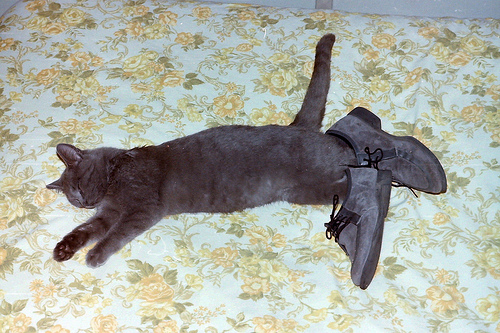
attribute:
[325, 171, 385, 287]
shoe — grey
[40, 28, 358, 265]
cat — pink , grey 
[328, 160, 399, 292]
shoe — grey, black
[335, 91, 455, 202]
shoe — grey, black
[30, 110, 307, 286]
cat — gray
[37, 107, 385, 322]
cat — sleeping, black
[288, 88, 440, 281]
shoes — grey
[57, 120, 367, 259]
cat — sleeping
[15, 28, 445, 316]
comforter — floral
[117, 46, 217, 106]
flower — yellow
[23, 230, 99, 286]
paws — padded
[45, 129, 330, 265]
cat — black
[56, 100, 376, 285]
cat — black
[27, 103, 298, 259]
cat — black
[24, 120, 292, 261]
cat — grey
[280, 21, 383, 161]
tail — grey, long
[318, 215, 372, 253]
laces — tied, black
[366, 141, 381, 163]
shoe laces — Untied, black 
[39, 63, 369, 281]
cat — Big , grey , sleeping 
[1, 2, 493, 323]
table cloth — Floral , white 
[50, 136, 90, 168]
ear — Fury , grey 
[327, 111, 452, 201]
shoe — grey 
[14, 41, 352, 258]
cat — grey 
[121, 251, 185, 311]
flowers — bunch 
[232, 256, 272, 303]
flowers — bunch 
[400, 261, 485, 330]
flowers — bunch 